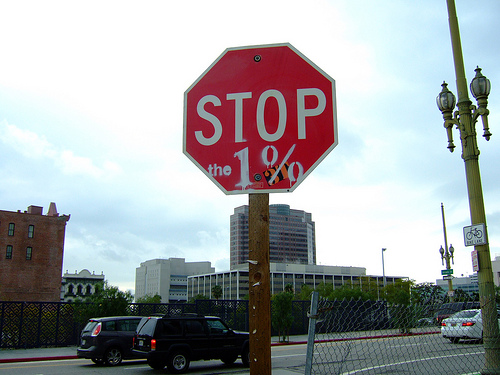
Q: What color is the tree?
A: Green.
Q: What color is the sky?
A: Blue.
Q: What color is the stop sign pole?
A: Brown.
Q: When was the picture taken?
A: Daytime.